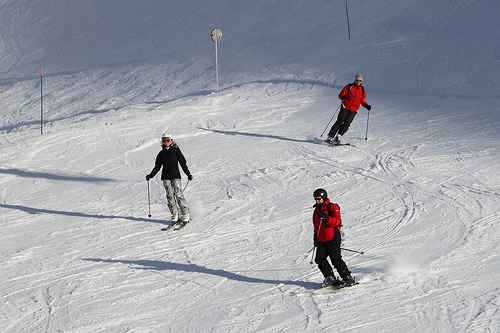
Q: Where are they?
A: Mountain.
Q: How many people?
A: Three.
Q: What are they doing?
A: Skiing.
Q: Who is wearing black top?
A: On left.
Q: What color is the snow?
A: White.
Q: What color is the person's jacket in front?
A: Red.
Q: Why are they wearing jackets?
A: Cold weather.